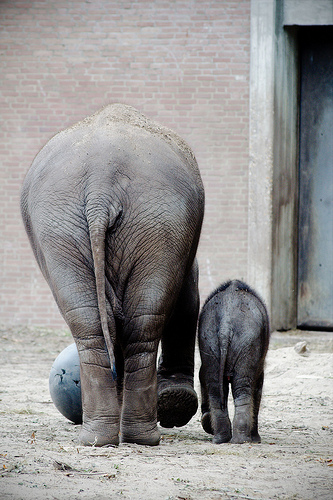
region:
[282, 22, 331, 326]
large metal door in wall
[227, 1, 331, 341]
concrete frame around metal door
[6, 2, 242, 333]
red brick wall in front of elephants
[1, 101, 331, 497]
two elephants walking in the dirt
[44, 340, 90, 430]
large ball on the ground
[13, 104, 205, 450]
adult elephant walking in the dirt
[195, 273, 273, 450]
baby elephant walking in the dirt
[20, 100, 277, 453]
adult and baby elephant walking side by side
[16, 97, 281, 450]
two elephants walking together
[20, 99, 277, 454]
two grey elephants walking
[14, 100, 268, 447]
Large and small elephant walking side by side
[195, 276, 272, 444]
The rear and tail of small elephant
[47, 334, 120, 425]
Black ball with some holes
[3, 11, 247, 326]
Red and white brick wall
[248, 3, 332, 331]
Metal door with wood frame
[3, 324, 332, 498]
Dirty brown ground with some grass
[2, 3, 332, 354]
Brick wall and door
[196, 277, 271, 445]
Small gray elephant with black fur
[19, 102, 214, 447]
Elephant with dirt on its back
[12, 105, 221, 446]
the back of an elephant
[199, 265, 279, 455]
a young elephant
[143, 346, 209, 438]
it's foot is lifted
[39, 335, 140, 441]
a big black ball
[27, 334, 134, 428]
a black rubber ball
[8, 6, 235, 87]
part of a brick wall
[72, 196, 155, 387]
the tail of a large elephant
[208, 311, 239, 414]
the tail of a young elephant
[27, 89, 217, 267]
there is dirt on top of this elephant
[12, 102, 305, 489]
the elephants have cracked skin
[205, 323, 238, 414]
tail of an elephant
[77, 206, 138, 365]
tail of an elephant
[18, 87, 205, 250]
body of an elephant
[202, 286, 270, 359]
body of an elephant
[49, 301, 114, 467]
leg of an elephant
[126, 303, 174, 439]
leg of an elephant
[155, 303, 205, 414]
leg of an elephant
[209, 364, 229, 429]
leg of an elephant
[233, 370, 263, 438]
leg of an elephant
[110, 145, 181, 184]
skin of an elephant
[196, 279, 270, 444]
A baby elephant walking.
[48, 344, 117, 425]
A large blue round ball.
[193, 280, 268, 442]
baby elephant sanding in the ground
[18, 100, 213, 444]
big elephant standing in the ground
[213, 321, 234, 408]
small tail of baby elephant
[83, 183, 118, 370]
large tail of big gray elephant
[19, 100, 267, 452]
two elephants walking together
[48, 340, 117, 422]
blue round ball in front of big gray elephant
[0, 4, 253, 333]
red bricked wall in front of elephants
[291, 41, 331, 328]
dark rusty metal door in front of elephants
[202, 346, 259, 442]
back legs of baby elephant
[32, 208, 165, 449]
back legs of big elephant